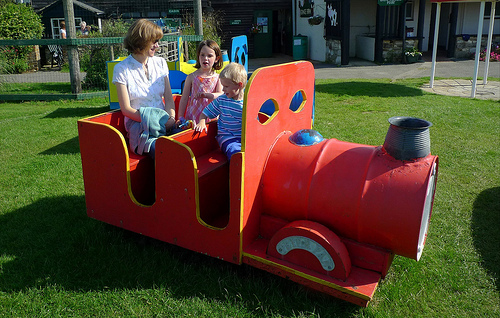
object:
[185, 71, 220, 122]
dress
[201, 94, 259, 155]
shirt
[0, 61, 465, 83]
road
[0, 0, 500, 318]
background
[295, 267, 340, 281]
color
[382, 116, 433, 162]
spout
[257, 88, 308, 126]
design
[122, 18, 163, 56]
hair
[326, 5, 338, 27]
animal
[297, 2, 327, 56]
wall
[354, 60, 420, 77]
color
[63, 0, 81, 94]
post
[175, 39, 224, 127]
children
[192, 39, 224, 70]
hair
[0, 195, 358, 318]
shadow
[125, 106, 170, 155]
sweater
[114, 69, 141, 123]
arm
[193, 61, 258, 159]
boy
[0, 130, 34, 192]
grass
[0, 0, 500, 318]
park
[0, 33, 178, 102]
fence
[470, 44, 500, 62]
flowers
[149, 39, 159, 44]
glasses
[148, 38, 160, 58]
face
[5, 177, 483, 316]
ground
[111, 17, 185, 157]
people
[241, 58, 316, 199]
wood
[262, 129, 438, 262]
tank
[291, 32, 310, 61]
can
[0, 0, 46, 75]
bushes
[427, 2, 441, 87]
poles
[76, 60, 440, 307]
train